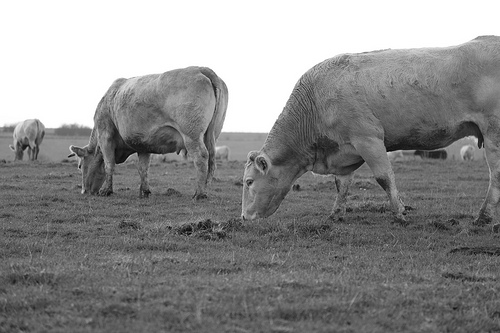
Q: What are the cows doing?
A: Eating grass.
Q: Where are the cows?
A: Outside in a field.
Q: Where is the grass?
A: In the field.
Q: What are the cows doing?
A: Grazing.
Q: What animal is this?
A: Cows.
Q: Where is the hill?
A: In the far background.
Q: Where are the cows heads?
A: Down.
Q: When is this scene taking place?
A: Daytime.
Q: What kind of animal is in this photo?
A: Cow.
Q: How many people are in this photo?
A: None.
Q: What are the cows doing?
A: Grazing.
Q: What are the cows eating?
A: Grass.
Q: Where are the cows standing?
A: Field.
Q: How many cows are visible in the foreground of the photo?
A: Three.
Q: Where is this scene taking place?
A: Ocean.